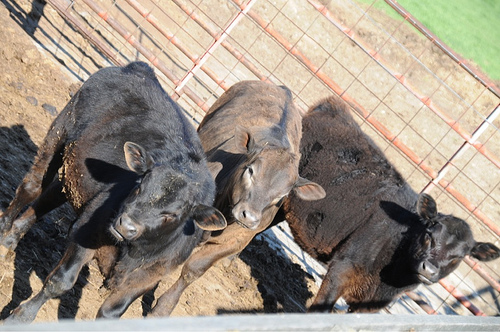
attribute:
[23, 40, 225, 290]
cow — brown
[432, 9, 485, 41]
grass — green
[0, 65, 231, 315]
cow — black, dirty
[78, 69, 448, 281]
cow — smaller, brown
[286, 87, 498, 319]
cow — black